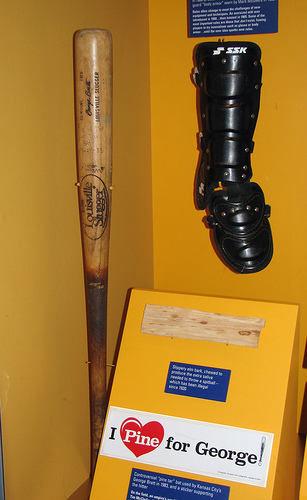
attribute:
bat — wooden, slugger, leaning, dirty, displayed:
[58, 40, 108, 225]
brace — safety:
[164, 54, 261, 210]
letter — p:
[116, 423, 141, 458]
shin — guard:
[169, 82, 285, 180]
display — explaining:
[110, 328, 262, 492]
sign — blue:
[173, 0, 303, 32]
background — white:
[178, 406, 237, 450]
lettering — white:
[164, 358, 219, 394]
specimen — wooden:
[54, 25, 158, 310]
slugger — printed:
[66, 170, 145, 253]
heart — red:
[108, 401, 166, 478]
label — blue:
[149, 341, 300, 436]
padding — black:
[163, 54, 305, 254]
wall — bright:
[140, 62, 271, 244]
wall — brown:
[7, 100, 69, 280]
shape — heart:
[101, 412, 195, 482]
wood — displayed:
[0, 40, 144, 374]